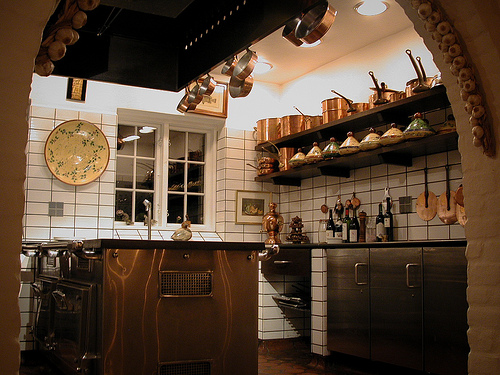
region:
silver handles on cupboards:
[320, 255, 422, 340]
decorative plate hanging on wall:
[11, 115, 107, 231]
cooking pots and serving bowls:
[240, 95, 452, 167]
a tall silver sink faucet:
[114, 187, 164, 247]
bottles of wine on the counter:
[285, 190, 402, 240]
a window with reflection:
[92, 128, 224, 220]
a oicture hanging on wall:
[202, 182, 287, 236]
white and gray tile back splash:
[38, 186, 102, 231]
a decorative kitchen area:
[8, 95, 418, 374]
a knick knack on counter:
[162, 209, 211, 251]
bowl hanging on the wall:
[35, 109, 116, 179]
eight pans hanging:
[169, 10, 336, 113]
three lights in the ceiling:
[244, 0, 394, 84]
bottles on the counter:
[319, 190, 414, 259]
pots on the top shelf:
[259, 71, 468, 147]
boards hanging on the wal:
[412, 169, 476, 234]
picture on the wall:
[235, 193, 297, 238]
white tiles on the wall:
[36, 190, 135, 228]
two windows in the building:
[118, 110, 233, 236]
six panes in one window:
[114, 117, 157, 224]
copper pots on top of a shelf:
[242, 111, 317, 140]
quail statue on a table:
[154, 208, 204, 250]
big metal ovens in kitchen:
[27, 263, 100, 358]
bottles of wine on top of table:
[317, 192, 406, 248]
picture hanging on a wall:
[230, 185, 279, 247]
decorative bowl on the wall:
[33, 113, 120, 200]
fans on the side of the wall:
[406, 167, 469, 229]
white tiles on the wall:
[82, 197, 109, 221]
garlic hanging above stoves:
[14, 0, 91, 90]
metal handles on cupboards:
[337, 256, 381, 299]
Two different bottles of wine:
[374, 194, 393, 241]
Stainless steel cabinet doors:
[327, 247, 467, 367]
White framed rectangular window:
[165, 123, 209, 223]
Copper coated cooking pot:
[255, 114, 278, 144]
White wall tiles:
[61, 191, 112, 236]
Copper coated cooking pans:
[228, 47, 255, 99]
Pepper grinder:
[358, 207, 368, 244]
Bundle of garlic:
[460, 65, 482, 117]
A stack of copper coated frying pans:
[251, 153, 276, 173]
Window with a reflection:
[117, 121, 154, 221]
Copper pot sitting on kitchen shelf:
[251, 114, 287, 144]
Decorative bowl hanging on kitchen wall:
[42, 112, 110, 203]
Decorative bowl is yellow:
[47, 113, 109, 195]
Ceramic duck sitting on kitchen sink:
[166, 214, 197, 246]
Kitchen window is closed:
[113, 107, 165, 234]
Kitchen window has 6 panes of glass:
[114, 113, 161, 234]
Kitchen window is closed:
[165, 115, 219, 232]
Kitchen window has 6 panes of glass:
[164, 117, 211, 234]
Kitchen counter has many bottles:
[319, 192, 399, 247]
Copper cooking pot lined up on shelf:
[283, 52, 449, 136]